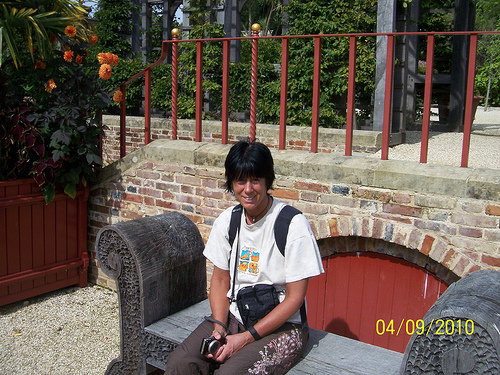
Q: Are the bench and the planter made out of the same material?
A: No, the bench is made of cement and the planter is made of wood.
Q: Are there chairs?
A: No, there are no chairs.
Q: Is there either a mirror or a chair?
A: No, there are no chairs or mirrors.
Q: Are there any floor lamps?
A: No, there are no floor lamps.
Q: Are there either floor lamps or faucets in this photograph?
A: No, there are no floor lamps or faucets.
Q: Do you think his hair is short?
A: Yes, the hair is short.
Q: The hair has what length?
A: The hair is short.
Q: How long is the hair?
A: The hair is short.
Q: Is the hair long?
A: No, the hair is short.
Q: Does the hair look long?
A: No, the hair is short.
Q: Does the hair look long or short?
A: The hair is short.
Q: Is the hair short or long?
A: The hair is short.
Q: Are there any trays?
A: No, there are no trays.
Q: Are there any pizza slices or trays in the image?
A: No, there are no trays or pizza slices.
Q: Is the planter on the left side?
A: Yes, the planter is on the left of the image.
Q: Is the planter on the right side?
A: No, the planter is on the left of the image.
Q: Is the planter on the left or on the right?
A: The planter is on the left of the image.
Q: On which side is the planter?
A: The planter is on the left of the image.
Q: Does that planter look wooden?
A: Yes, the planter is wooden.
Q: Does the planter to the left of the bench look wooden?
A: Yes, the planter is wooden.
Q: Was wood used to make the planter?
A: Yes, the planter is made of wood.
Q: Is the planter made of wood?
A: Yes, the planter is made of wood.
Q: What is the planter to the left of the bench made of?
A: The planter is made of wood.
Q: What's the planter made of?
A: The planter is made of wood.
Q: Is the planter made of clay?
A: No, the planter is made of wood.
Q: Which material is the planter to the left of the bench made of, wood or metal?
A: The planter is made of wood.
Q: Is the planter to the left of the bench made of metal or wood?
A: The planter is made of wood.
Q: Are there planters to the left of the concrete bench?
A: Yes, there is a planter to the left of the bench.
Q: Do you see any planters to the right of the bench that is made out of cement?
A: No, the planter is to the left of the bench.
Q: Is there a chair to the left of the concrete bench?
A: No, there is a planter to the left of the bench.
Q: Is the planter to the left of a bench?
A: Yes, the planter is to the left of a bench.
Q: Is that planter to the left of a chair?
A: No, the planter is to the left of a bench.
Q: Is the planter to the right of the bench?
A: No, the planter is to the left of the bench.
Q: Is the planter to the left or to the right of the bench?
A: The planter is to the left of the bench.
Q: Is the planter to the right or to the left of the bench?
A: The planter is to the left of the bench.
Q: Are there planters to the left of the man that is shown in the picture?
A: Yes, there is a planter to the left of the man.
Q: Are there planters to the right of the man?
A: No, the planter is to the left of the man.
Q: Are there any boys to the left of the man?
A: No, there is a planter to the left of the man.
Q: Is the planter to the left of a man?
A: Yes, the planter is to the left of a man.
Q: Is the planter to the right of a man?
A: No, the planter is to the left of a man.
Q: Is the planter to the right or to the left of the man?
A: The planter is to the left of the man.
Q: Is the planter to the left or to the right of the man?
A: The planter is to the left of the man.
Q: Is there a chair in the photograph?
A: No, there are no chairs.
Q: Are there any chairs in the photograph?
A: No, there are no chairs.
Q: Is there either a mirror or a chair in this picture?
A: No, there are no chairs or mirrors.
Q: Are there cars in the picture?
A: No, there are no cars.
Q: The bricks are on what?
A: The bricks are on the walls.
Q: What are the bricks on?
A: The bricks are on the walls.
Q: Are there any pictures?
A: No, there are no pictures.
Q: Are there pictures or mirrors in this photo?
A: No, there are no pictures or mirrors.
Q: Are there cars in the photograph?
A: No, there are no cars.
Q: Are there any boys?
A: No, there are no boys.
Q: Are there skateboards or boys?
A: No, there are no boys or skateboards.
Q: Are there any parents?
A: No, there are no parents.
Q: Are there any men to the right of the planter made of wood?
A: Yes, there is a man to the right of the planter.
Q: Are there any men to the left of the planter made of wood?
A: No, the man is to the right of the planter.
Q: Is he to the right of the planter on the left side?
A: Yes, the man is to the right of the planter.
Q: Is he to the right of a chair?
A: No, the man is to the right of the planter.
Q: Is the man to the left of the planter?
A: No, the man is to the right of the planter.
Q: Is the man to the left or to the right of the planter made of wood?
A: The man is to the right of the planter.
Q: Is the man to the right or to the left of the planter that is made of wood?
A: The man is to the right of the planter.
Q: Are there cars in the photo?
A: No, there are no cars.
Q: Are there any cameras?
A: Yes, there is a camera.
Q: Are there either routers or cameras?
A: Yes, there is a camera.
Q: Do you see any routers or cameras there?
A: Yes, there is a camera.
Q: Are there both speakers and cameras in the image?
A: No, there is a camera but no speakers.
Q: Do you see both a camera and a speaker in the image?
A: No, there is a camera but no speakers.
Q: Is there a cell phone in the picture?
A: No, there are no cell phones.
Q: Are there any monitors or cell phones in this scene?
A: No, there are no cell phones or monitors.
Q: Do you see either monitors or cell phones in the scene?
A: No, there are no cell phones or monitors.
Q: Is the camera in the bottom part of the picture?
A: Yes, the camera is in the bottom of the image.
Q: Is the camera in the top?
A: No, the camera is in the bottom of the image.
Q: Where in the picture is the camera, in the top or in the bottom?
A: The camera is in the bottom of the image.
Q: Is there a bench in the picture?
A: Yes, there is a bench.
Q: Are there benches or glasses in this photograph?
A: Yes, there is a bench.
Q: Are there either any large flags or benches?
A: Yes, there is a large bench.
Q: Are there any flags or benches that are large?
A: Yes, the bench is large.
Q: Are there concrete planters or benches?
A: Yes, there is a concrete bench.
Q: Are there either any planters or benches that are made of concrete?
A: Yes, the bench is made of concrete.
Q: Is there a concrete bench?
A: Yes, there is a bench that is made of concrete.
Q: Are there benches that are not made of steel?
A: Yes, there is a bench that is made of cement.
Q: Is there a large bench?
A: Yes, there is a large bench.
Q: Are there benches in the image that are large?
A: Yes, there is a bench that is large.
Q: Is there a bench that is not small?
A: Yes, there is a large bench.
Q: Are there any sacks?
A: No, there are no sacks.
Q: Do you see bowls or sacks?
A: No, there are no sacks or bowls.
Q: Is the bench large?
A: Yes, the bench is large.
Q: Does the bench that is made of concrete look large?
A: Yes, the bench is large.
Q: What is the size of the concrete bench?
A: The bench is large.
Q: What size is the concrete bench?
A: The bench is large.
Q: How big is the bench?
A: The bench is large.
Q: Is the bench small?
A: No, the bench is large.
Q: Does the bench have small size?
A: No, the bench is large.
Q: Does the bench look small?
A: No, the bench is large.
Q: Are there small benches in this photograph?
A: No, there is a bench but it is large.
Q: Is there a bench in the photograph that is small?
A: No, there is a bench but it is large.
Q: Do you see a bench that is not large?
A: No, there is a bench but it is large.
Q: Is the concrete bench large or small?
A: The bench is large.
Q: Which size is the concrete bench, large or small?
A: The bench is large.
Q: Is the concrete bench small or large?
A: The bench is large.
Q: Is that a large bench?
A: Yes, that is a large bench.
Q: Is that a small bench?
A: No, that is a large bench.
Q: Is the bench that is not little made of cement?
A: Yes, the bench is made of cement.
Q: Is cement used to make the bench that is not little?
A: Yes, the bench is made of cement.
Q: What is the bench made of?
A: The bench is made of concrete.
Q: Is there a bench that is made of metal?
A: No, there is a bench but it is made of cement.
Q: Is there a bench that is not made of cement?
A: No, there is a bench but it is made of cement.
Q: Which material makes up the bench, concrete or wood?
A: The bench is made of concrete.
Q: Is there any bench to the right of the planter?
A: Yes, there is a bench to the right of the planter.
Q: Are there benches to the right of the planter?
A: Yes, there is a bench to the right of the planter.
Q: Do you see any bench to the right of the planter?
A: Yes, there is a bench to the right of the planter.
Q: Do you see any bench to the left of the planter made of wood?
A: No, the bench is to the right of the planter.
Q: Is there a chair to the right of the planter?
A: No, there is a bench to the right of the planter.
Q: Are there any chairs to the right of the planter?
A: No, there is a bench to the right of the planter.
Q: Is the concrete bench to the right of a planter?
A: Yes, the bench is to the right of a planter.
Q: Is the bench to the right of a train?
A: No, the bench is to the right of a planter.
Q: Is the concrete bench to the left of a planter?
A: No, the bench is to the right of a planter.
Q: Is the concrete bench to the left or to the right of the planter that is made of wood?
A: The bench is to the right of the planter.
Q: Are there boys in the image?
A: No, there are no boys.